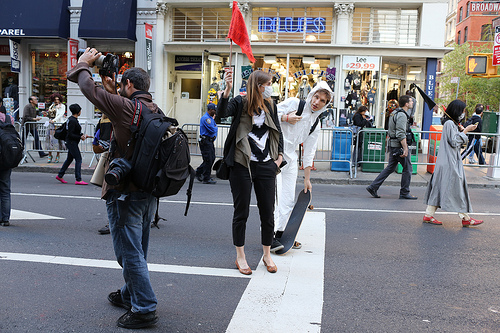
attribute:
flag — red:
[224, 5, 256, 65]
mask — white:
[256, 80, 276, 104]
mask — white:
[457, 111, 465, 122]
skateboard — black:
[273, 189, 317, 255]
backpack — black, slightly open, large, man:
[127, 94, 201, 218]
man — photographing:
[64, 42, 178, 328]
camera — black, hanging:
[101, 154, 134, 186]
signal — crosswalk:
[464, 53, 493, 82]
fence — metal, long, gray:
[2, 117, 500, 180]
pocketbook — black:
[211, 154, 233, 185]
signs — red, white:
[493, 24, 500, 66]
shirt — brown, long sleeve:
[65, 62, 173, 202]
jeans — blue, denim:
[104, 182, 167, 315]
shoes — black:
[117, 304, 162, 329]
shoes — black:
[103, 284, 140, 318]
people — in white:
[261, 73, 336, 260]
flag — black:
[413, 85, 436, 113]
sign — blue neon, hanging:
[254, 12, 327, 44]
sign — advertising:
[339, 52, 383, 76]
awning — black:
[76, 1, 137, 49]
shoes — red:
[461, 215, 485, 232]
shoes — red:
[421, 211, 445, 227]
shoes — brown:
[260, 252, 282, 275]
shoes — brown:
[234, 257, 252, 278]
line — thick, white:
[219, 201, 336, 333]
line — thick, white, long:
[1, 247, 258, 282]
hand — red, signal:
[467, 55, 479, 75]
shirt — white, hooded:
[273, 76, 336, 176]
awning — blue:
[1, 1, 71, 45]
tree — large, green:
[435, 43, 500, 123]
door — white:
[171, 70, 207, 136]